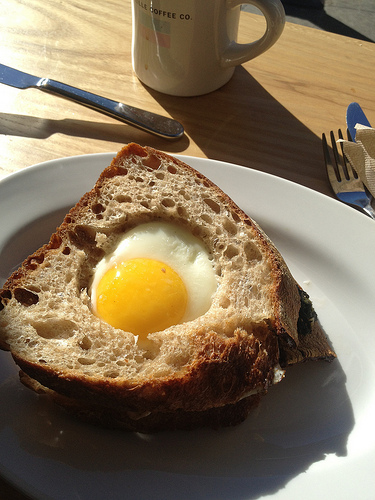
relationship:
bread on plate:
[0, 141, 302, 416] [2, 150, 374, 498]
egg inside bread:
[91, 219, 219, 334] [4, 140, 303, 414]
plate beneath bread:
[2, 150, 374, 498] [0, 141, 302, 416]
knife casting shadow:
[0, 62, 185, 140] [4, 115, 190, 147]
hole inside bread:
[32, 313, 79, 340] [7, 137, 319, 436]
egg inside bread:
[91, 219, 219, 334] [7, 137, 319, 436]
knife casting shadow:
[0, 62, 185, 140] [2, 107, 185, 145]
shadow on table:
[2, 107, 185, 145] [1, 38, 373, 186]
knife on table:
[0, 62, 185, 140] [1, 38, 373, 186]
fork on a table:
[321, 128, 375, 217] [267, 76, 318, 142]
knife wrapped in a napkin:
[348, 100, 368, 133] [362, 138, 370, 174]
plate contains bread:
[0, 150, 374, 498] [0, 141, 302, 416]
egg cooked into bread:
[75, 230, 205, 335] [38, 323, 265, 427]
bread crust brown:
[0, 141, 302, 416] [81, 345, 252, 402]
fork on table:
[321, 121, 373, 217] [1, 2, 374, 497]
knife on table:
[345, 102, 373, 143] [1, 2, 374, 497]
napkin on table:
[333, 121, 373, 202] [1, 2, 374, 497]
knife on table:
[1, 59, 185, 140] [1, 2, 374, 497]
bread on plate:
[7, 137, 319, 436] [2, 150, 374, 498]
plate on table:
[2, 150, 374, 498] [1, 2, 374, 497]